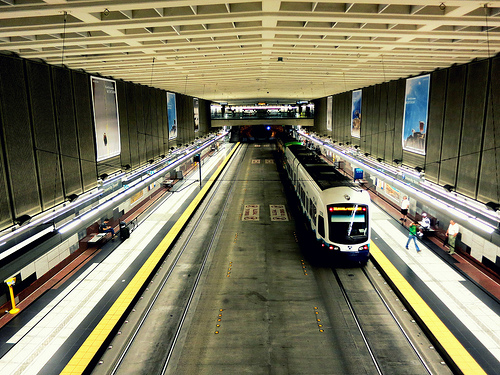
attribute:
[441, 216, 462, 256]
person — standing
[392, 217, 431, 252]
person — standing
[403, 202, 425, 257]
person — standing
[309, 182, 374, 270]
train engine — white  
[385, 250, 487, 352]
line —  yellow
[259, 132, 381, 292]
train car — white  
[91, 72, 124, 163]
poster — large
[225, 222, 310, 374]
ground — grey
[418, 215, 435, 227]
shirt — white